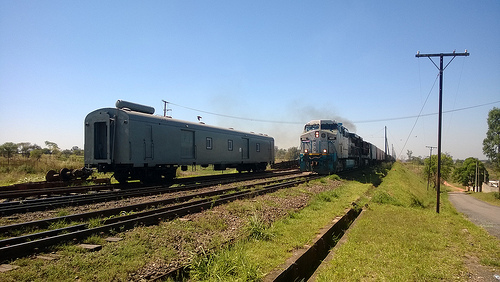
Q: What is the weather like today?
A: It is clear.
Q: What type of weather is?
A: It is clear.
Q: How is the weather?
A: It is clear.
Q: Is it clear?
A: Yes, it is clear.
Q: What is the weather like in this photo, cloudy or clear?
A: It is clear.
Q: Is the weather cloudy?
A: No, it is clear.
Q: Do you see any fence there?
A: No, there are no fences.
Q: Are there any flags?
A: No, there are no flags.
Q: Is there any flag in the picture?
A: No, there are no flags.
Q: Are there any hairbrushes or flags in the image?
A: No, there are no flags or hairbrushes.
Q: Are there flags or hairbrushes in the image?
A: No, there are no flags or hairbrushes.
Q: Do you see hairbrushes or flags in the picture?
A: No, there are no flags or hairbrushes.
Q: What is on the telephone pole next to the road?
A: The power line is on the telephone pole.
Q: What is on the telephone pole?
A: The power line is on the telephone pole.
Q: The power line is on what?
A: The power line is on the utility pole.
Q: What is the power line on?
A: The power line is on the utility pole.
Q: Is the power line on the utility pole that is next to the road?
A: Yes, the power line is on the utility pole.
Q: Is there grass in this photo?
A: Yes, there is grass.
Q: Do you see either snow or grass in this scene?
A: Yes, there is grass.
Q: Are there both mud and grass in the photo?
A: No, there is grass but no mud.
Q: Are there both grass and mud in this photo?
A: No, there is grass but no mud.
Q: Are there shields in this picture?
A: No, there are no shields.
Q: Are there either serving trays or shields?
A: No, there are no shields or serving trays.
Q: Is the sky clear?
A: Yes, the sky is clear.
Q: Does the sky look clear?
A: Yes, the sky is clear.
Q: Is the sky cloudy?
A: No, the sky is clear.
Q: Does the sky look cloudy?
A: No, the sky is clear.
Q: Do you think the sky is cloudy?
A: No, the sky is clear.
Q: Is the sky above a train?
A: Yes, the sky is above a train.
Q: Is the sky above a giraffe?
A: No, the sky is above a train.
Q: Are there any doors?
A: Yes, there is a door.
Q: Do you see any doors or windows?
A: Yes, there is a door.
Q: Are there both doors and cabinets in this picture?
A: No, there is a door but no cabinets.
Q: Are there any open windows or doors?
A: Yes, there is an open door.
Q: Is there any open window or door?
A: Yes, there is an open door.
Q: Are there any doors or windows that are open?
A: Yes, the door is open.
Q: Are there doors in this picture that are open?
A: Yes, there is an open door.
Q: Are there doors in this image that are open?
A: Yes, there is a door that is open.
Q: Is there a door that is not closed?
A: Yes, there is a open door.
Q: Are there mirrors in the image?
A: No, there are no mirrors.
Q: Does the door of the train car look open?
A: Yes, the door is open.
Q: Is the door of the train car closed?
A: No, the door is open.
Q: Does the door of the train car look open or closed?
A: The door is open.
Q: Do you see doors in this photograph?
A: Yes, there is a door.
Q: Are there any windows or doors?
A: Yes, there is a door.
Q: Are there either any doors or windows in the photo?
A: Yes, there is a door.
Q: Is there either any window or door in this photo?
A: Yes, there is a door.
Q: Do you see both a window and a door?
A: Yes, there are both a door and a window.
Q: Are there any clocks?
A: No, there are no clocks.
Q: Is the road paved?
A: Yes, the road is paved.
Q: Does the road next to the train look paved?
A: Yes, the road is paved.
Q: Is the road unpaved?
A: No, the road is paved.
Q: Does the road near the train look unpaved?
A: No, the road is paved.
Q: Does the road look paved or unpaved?
A: The road is paved.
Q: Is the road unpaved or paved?
A: The road is paved.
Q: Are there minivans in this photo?
A: No, there are no minivans.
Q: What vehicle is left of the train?
A: The vehicle is a train car.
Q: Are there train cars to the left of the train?
A: Yes, there is a train car to the left of the train.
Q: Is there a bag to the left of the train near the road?
A: No, there is a train car to the left of the train.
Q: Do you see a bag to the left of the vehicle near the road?
A: No, there is a train car to the left of the train.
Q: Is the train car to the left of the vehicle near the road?
A: Yes, the train car is to the left of the train.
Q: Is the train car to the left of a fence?
A: No, the train car is to the left of the train.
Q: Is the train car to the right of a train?
A: No, the train car is to the left of a train.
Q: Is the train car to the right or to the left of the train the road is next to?
A: The train car is to the left of the train.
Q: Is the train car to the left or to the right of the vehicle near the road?
A: The train car is to the left of the train.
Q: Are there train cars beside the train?
A: Yes, there is a train car beside the train.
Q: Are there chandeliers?
A: No, there are no chandeliers.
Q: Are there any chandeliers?
A: No, there are no chandeliers.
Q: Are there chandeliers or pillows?
A: No, there are no chandeliers or pillows.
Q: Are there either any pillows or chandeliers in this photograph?
A: No, there are no chandeliers or pillows.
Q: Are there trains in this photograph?
A: Yes, there is a train.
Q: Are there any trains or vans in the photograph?
A: Yes, there is a train.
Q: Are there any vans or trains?
A: Yes, there is a train.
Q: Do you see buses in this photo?
A: No, there are no buses.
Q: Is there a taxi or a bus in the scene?
A: No, there are no buses or taxis.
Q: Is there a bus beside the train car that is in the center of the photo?
A: No, there is a train beside the train car.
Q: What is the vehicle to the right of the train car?
A: The vehicle is a train.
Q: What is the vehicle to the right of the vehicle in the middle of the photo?
A: The vehicle is a train.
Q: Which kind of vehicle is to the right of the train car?
A: The vehicle is a train.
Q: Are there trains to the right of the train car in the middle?
A: Yes, there is a train to the right of the train car.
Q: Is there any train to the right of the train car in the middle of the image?
A: Yes, there is a train to the right of the train car.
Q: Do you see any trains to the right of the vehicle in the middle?
A: Yes, there is a train to the right of the train car.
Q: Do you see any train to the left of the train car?
A: No, the train is to the right of the train car.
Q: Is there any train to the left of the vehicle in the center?
A: No, the train is to the right of the train car.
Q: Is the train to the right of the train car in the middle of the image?
A: Yes, the train is to the right of the train car.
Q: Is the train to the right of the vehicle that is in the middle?
A: Yes, the train is to the right of the train car.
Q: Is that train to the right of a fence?
A: No, the train is to the right of the train car.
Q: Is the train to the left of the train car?
A: No, the train is to the right of the train car.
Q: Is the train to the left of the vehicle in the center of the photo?
A: No, the train is to the right of the train car.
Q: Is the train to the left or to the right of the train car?
A: The train is to the right of the train car.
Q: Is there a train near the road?
A: Yes, there is a train near the road.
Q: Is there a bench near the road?
A: No, there is a train near the road.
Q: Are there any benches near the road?
A: No, there is a train near the road.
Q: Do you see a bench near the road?
A: No, there is a train near the road.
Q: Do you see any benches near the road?
A: No, there is a train near the road.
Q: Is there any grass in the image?
A: Yes, there is grass.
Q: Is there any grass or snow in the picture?
A: Yes, there is grass.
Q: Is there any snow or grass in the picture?
A: Yes, there is grass.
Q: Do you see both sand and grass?
A: No, there is grass but no sand.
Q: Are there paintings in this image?
A: No, there are no paintings.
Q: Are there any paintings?
A: No, there are no paintings.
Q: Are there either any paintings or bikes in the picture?
A: No, there are no paintings or bikes.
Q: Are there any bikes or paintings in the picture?
A: No, there are no paintings or bikes.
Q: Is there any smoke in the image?
A: Yes, there is smoke.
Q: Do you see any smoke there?
A: Yes, there is smoke.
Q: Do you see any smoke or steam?
A: Yes, there is smoke.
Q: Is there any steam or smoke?
A: Yes, there is smoke.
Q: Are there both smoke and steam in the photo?
A: No, there is smoke but no steam.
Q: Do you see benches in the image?
A: No, there are no benches.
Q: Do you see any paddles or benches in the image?
A: No, there are no benches or paddles.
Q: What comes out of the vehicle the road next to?
A: The smoke comes out of the train.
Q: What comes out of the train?
A: The smoke comes out of the train.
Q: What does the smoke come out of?
A: The smoke comes out of the train.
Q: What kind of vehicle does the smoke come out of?
A: The smoke comes out of the train.